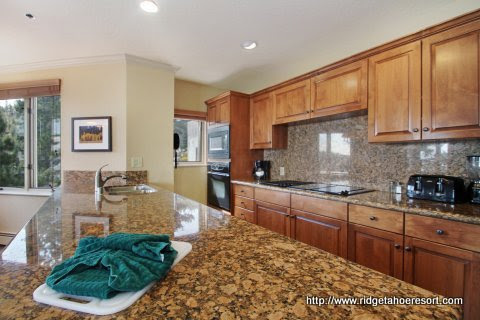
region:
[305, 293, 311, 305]
white print style letter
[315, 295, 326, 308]
white print style letter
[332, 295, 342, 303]
white print style letter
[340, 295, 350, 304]
white print style letter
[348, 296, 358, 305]
white print style letter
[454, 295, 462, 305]
white print style letter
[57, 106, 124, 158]
portrait on wall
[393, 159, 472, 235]
black toaster on table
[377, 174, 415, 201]
salt and pepper shaker on table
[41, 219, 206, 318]
green towel on table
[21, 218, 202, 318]
white cutting board on table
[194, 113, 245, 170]
black microwave in cabinet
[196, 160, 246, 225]
black oven in cabinet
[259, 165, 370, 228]
stove tops on counter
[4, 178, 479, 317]
granite table top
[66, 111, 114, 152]
picture hanging on wall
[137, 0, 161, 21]
recessed light in ceiling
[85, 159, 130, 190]
silver metal sink faucet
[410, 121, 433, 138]
metal knobs on cabinet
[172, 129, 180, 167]
black phone hanging on wall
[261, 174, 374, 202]
black stove top on counter top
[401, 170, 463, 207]
black toaster sitting on counter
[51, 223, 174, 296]
green towel sitting on cutting board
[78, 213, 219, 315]
green towel on table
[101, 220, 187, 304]
white board on table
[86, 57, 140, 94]
wall is light brown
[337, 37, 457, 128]
brown cabinets over sink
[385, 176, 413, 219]
brown and black counter near sink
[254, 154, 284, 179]
coffee pot is black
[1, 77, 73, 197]
windows next to picture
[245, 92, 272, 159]
wood door on cabinet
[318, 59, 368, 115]
wood door on cabinet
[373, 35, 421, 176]
wood door on cabinet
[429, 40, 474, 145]
wood door on cabinet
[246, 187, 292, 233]
wood door on cabinet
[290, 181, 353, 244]
wood door on cabinet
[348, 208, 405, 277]
wood door on cabinet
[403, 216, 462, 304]
wood door on cabinet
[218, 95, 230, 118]
wood door on cabinet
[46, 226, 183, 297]
green towel on white cutting board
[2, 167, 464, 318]
granite style kitchen counter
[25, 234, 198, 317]
white cutting board on counter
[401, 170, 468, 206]
black toaster on counter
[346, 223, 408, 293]
A door for a cabinet.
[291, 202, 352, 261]
A door for a cabinet.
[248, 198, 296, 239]
A door for a cabinet.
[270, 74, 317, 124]
A door for a cabinet.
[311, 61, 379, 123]
A door for a cabinet.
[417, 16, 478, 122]
A door for a cabinet.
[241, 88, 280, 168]
A door for a cabinet.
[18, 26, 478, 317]
A kitchen.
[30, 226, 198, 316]
A white cutting board.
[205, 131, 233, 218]
A stove built into the wall.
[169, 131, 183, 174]
A black corded phone.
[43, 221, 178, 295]
A green dish towel.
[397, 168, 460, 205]
A black double toaster.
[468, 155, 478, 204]
A blender.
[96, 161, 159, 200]
A kitchen sink.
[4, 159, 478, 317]
Brown marble countertops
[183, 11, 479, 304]
Brown wooden kitchen cabinets.